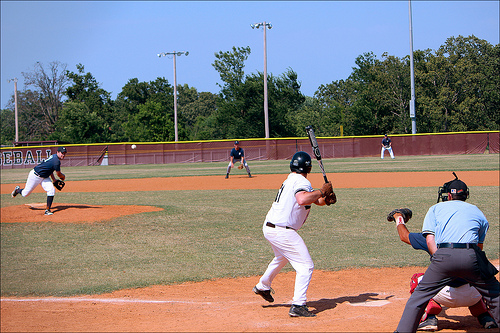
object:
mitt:
[387, 207, 413, 223]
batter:
[252, 151, 332, 317]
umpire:
[393, 179, 499, 333]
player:
[12, 146, 68, 215]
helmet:
[290, 151, 312, 173]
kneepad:
[410, 272, 425, 294]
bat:
[305, 125, 336, 203]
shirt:
[34, 154, 62, 178]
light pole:
[147, 1, 430, 141]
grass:
[0, 151, 499, 295]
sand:
[4, 170, 499, 333]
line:
[0, 289, 403, 333]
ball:
[131, 144, 137, 149]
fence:
[5, 131, 500, 168]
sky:
[1, 1, 499, 111]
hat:
[56, 146, 66, 160]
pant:
[394, 245, 500, 333]